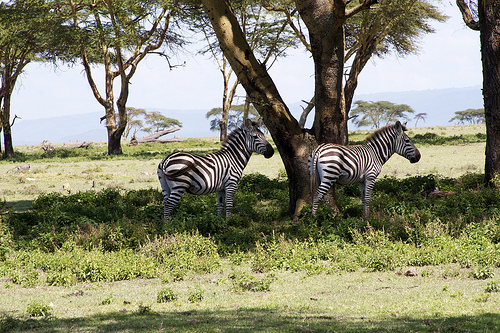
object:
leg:
[312, 173, 339, 213]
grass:
[0, 123, 500, 333]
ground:
[0, 124, 499, 333]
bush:
[40, 145, 94, 158]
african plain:
[0, 124, 498, 332]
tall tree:
[39, 0, 186, 155]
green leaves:
[0, 0, 122, 64]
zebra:
[308, 121, 421, 218]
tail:
[162, 152, 198, 178]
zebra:
[157, 117, 274, 221]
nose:
[415, 153, 421, 162]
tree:
[163, 0, 450, 223]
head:
[244, 118, 274, 158]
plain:
[0, 124, 500, 333]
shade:
[0, 306, 500, 333]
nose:
[267, 149, 274, 157]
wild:
[0, 87, 500, 333]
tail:
[312, 154, 317, 204]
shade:
[0, 173, 500, 256]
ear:
[245, 119, 253, 130]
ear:
[256, 118, 263, 127]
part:
[306, 177, 335, 227]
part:
[295, 279, 359, 310]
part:
[311, 174, 316, 204]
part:
[470, 311, 500, 331]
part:
[271, 296, 320, 319]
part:
[139, 235, 215, 276]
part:
[367, 150, 378, 164]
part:
[36, 151, 72, 160]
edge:
[0, 313, 497, 333]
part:
[27, 254, 98, 270]